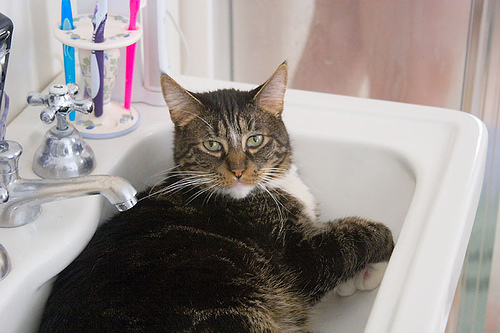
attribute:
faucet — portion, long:
[2, 82, 139, 233]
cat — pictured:
[37, 60, 394, 331]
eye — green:
[243, 130, 265, 149]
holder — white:
[36, 23, 151, 120]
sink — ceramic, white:
[16, 80, 486, 331]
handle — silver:
[26, 80, 98, 180]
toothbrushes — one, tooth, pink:
[44, 0, 164, 145]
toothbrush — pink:
[43, 4, 165, 140]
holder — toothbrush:
[54, 9, 145, 125]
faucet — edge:
[3, 128, 139, 227]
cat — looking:
[131, 60, 369, 315]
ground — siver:
[315, 160, 352, 190]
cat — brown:
[161, 87, 327, 249]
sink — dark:
[0, 31, 498, 331]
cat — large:
[50, 82, 384, 331]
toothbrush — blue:
[51, 5, 96, 100]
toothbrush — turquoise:
[59, 1, 136, 116]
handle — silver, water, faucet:
[27, 73, 104, 134]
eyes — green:
[195, 127, 278, 158]